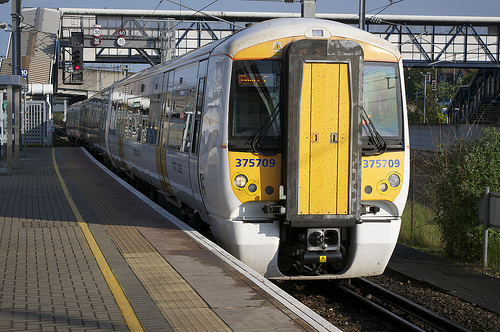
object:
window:
[231, 73, 281, 140]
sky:
[0, 0, 394, 8]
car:
[66, 17, 411, 280]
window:
[110, 95, 150, 143]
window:
[362, 67, 402, 142]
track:
[64, 17, 408, 281]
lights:
[238, 73, 273, 87]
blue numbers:
[236, 159, 276, 168]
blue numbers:
[363, 159, 400, 168]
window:
[167, 77, 204, 155]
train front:
[222, 17, 410, 280]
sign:
[20, 69, 28, 77]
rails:
[337, 276, 474, 332]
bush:
[424, 141, 500, 259]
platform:
[386, 243, 500, 315]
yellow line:
[51, 147, 144, 332]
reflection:
[109, 55, 222, 210]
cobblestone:
[328, 301, 354, 316]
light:
[232, 174, 248, 188]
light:
[75, 66, 80, 70]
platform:
[0, 145, 344, 332]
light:
[248, 183, 257, 193]